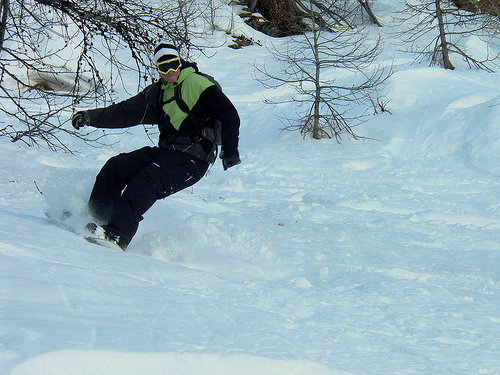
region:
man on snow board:
[72, 39, 243, 247]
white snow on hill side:
[265, 232, 336, 287]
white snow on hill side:
[360, 271, 394, 315]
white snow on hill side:
[247, 288, 294, 366]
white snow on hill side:
[45, 296, 116, 340]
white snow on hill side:
[400, 159, 475, 220]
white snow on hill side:
[305, 218, 360, 265]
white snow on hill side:
[274, 266, 368, 327]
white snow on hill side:
[225, 273, 257, 320]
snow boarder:
[42, 38, 252, 273]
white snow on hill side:
[294, 323, 359, 363]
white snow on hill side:
[360, 287, 395, 317]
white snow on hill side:
[404, 214, 438, 261]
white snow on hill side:
[172, 303, 223, 350]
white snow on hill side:
[91, 305, 143, 352]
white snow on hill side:
[232, 214, 274, 249]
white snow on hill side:
[300, 195, 321, 218]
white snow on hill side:
[362, 171, 422, 231]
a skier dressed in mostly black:
[69, 38, 241, 252]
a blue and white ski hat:
[150, 43, 180, 63]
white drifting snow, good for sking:
[242, 146, 493, 373]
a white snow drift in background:
[387, 68, 499, 173]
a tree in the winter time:
[381, 0, 498, 77]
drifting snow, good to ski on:
[0, 251, 497, 373]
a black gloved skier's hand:
[69, 109, 88, 131]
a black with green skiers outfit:
[81, 65, 243, 253]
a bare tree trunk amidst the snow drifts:
[226, 0, 383, 37]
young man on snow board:
[68, 25, 253, 247]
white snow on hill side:
[340, 308, 425, 368]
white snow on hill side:
[344, 269, 396, 324]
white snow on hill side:
[394, 196, 435, 258]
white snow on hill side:
[134, 268, 202, 310]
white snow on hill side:
[28, 266, 95, 317]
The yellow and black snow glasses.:
[157, 56, 182, 75]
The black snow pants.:
[86, 144, 212, 237]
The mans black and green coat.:
[76, 85, 255, 182]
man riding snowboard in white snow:
[35, 44, 251, 254]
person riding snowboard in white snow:
[51, 38, 251, 255]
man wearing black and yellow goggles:
[151, 54, 187, 76]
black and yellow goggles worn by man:
[153, 57, 187, 79]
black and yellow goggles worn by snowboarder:
[149, 54, 184, 75]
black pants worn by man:
[74, 147, 208, 225]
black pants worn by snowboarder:
[89, 145, 203, 219]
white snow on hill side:
[278, 252, 308, 277]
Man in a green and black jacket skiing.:
[65, 45, 245, 253]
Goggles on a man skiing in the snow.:
[154, 55, 185, 72]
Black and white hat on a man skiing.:
[151, 41, 182, 61]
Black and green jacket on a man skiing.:
[70, 66, 252, 166]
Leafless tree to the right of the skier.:
[257, 2, 385, 141]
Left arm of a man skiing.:
[200, 77, 255, 169]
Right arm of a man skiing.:
[71, 81, 156, 128]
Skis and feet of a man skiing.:
[39, 201, 140, 251]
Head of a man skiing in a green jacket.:
[150, 43, 185, 82]